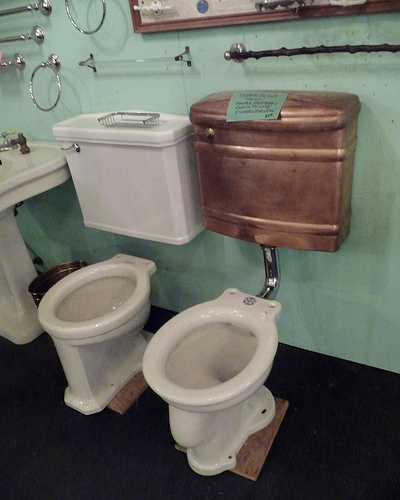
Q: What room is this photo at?
A: It is at the bathroom.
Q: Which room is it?
A: It is a bathroom.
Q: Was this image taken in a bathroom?
A: Yes, it was taken in a bathroom.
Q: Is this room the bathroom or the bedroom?
A: It is the bathroom.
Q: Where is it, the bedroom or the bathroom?
A: It is the bathroom.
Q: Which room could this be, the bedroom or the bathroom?
A: It is the bathroom.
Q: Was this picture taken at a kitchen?
A: No, the picture was taken in a bathroom.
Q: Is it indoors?
A: Yes, it is indoors.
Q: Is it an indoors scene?
A: Yes, it is indoors.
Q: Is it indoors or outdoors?
A: It is indoors.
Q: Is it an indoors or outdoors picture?
A: It is indoors.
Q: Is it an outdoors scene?
A: No, it is indoors.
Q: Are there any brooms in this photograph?
A: No, there are no brooms.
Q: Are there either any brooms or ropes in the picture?
A: No, there are no brooms or ropes.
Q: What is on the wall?
A: The ring is on the wall.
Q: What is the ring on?
A: The ring is on the wall.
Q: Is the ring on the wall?
A: Yes, the ring is on the wall.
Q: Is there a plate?
A: No, there are no plates.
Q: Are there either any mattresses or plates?
A: No, there are no plates or mattresses.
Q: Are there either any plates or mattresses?
A: No, there are no plates or mattresses.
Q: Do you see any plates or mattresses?
A: No, there are no plates or mattresses.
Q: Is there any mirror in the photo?
A: No, there are no mirrors.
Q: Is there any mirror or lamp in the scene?
A: No, there are no mirrors or lamps.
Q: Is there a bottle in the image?
A: No, there are no bottles.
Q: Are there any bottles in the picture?
A: No, there are no bottles.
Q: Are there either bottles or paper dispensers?
A: No, there are no bottles or paper dispensers.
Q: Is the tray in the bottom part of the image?
A: No, the tray is in the top of the image.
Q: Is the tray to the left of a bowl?
A: No, the tray is to the left of a toilet.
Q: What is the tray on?
A: The tray is on the lid.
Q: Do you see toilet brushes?
A: No, there are no toilet brushes.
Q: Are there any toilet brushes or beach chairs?
A: No, there are no toilet brushes or beach chairs.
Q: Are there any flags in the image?
A: No, there are no flags.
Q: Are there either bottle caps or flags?
A: No, there are no flags or bottle caps.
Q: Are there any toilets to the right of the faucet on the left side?
A: Yes, there is a toilet to the right of the faucet.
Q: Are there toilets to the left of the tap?
A: No, the toilet is to the right of the tap.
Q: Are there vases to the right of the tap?
A: No, there is a toilet to the right of the tap.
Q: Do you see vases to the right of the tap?
A: No, there is a toilet to the right of the tap.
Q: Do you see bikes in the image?
A: No, there are no bikes.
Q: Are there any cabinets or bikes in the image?
A: No, there are no bikes or cabinets.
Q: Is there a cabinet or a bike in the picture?
A: No, there are no bikes or cabinets.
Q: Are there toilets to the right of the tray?
A: Yes, there is a toilet to the right of the tray.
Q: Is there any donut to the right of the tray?
A: No, there is a toilet to the right of the tray.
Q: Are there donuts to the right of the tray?
A: No, there is a toilet to the right of the tray.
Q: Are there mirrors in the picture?
A: No, there are no mirrors.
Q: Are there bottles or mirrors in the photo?
A: No, there are no mirrors or bottles.